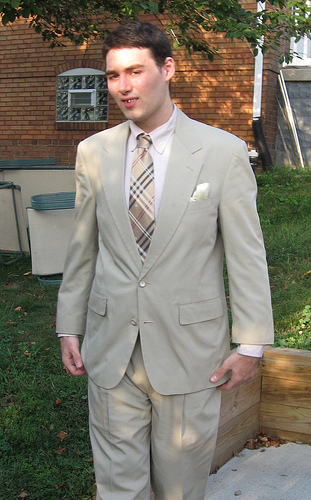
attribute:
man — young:
[56, 24, 275, 500]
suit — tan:
[56, 115, 273, 499]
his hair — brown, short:
[102, 17, 171, 62]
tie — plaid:
[128, 132, 156, 249]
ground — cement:
[209, 434, 311, 499]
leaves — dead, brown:
[248, 434, 281, 451]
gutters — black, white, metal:
[252, 2, 275, 174]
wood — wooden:
[262, 346, 310, 443]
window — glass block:
[52, 67, 108, 125]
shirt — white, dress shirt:
[153, 125, 170, 160]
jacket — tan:
[55, 108, 276, 395]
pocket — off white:
[176, 290, 226, 348]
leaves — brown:
[56, 429, 68, 443]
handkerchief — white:
[192, 180, 210, 198]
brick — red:
[1, 25, 55, 161]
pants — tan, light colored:
[87, 372, 225, 500]